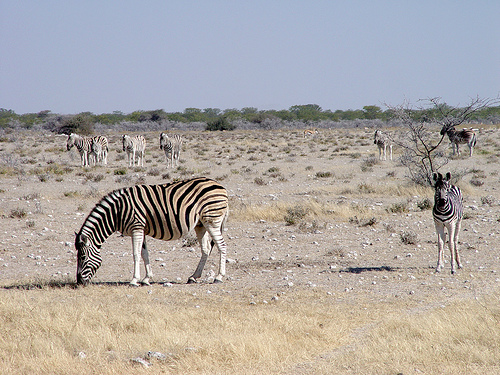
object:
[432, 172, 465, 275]
zebra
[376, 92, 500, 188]
tree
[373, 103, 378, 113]
leaves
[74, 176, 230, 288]
zebra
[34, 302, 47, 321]
patch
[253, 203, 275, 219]
grass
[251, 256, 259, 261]
rock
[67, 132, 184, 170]
group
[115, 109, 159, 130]
trees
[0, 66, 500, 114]
horizon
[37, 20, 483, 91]
skies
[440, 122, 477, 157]
zebra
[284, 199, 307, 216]
small bushes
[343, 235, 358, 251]
dirt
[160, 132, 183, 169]
zebra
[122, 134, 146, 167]
zebra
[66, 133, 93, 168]
zebra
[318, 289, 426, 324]
ground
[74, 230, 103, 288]
head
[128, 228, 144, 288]
legs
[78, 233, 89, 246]
ear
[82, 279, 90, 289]
mouth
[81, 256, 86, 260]
eye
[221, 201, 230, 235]
tail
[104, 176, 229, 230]
body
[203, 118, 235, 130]
bushes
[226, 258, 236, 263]
stones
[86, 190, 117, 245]
neck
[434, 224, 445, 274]
legs